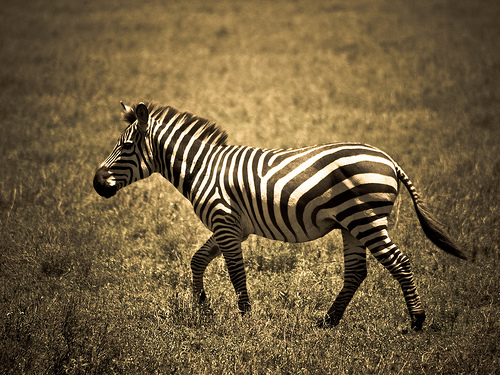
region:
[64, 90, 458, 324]
a zebra in a field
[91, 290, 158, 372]
green grass in a field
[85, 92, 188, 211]
a zebra's head facing left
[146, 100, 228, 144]
a black and white zebra mane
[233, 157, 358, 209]
black and white stripes on the side of a zebra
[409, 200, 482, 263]
the long hair of a zebra's tail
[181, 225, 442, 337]
four giraffe legs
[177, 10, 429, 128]
sunlight shining on the grass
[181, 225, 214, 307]
the front right leg of a zebra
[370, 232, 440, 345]
the back left leg of a zebra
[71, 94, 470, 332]
black and white striped zebra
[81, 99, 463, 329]
black and white striped zebra on plain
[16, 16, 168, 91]
green and brown grass on plain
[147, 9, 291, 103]
green and brown grass on plain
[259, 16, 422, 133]
green and brown grass on plain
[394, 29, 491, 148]
green and brown grass on plain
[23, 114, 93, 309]
green and brown grass on plain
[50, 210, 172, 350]
green and brown grass on plain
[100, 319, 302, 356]
green and brown grass on plain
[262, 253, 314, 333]
green and brown grass on plain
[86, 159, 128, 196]
The nose of the zebra in the field.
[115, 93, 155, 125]
The two ears of the zebra.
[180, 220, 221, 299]
The left front leg of the zebra.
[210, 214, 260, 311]
The front right leg of the zebra.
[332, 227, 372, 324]
The back left leg of the zebra.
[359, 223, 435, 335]
The back right leg of the zebra.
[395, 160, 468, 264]
The tail of the zebra.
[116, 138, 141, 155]
The eye of the zebra.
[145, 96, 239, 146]
The mane on the back of the zebra's neck.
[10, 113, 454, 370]
The pasture where the zebra is standing.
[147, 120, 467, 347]
zebra has black stripes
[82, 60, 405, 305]
zebra has black stripes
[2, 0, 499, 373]
photo with sepia filter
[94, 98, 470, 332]
zebra with black and white stripes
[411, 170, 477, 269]
black hair on tail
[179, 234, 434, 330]
thin black and white stripes on legs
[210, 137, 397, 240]
thick black and white stripes on back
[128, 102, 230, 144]
black and white hair on neck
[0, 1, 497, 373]
zebra standing on grass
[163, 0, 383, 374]
sunlight shines in middle of grass and zebra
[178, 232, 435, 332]
zebra's right legs in front of left legs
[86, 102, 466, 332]
zebra's head faces left